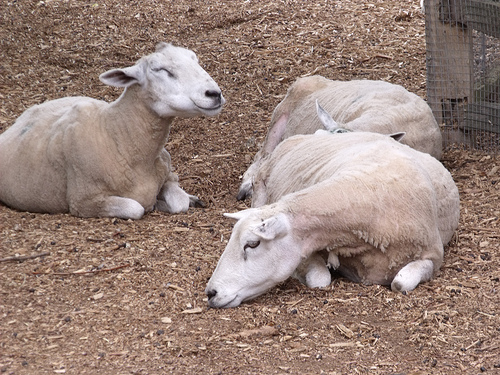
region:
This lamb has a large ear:
[257, 220, 284, 310]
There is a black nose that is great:
[207, 273, 229, 333]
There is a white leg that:
[163, 193, 182, 230]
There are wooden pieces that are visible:
[85, 285, 96, 314]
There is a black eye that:
[243, 228, 255, 251]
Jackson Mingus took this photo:
[138, 159, 226, 331]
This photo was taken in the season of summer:
[153, 143, 248, 367]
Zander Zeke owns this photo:
[166, 122, 223, 359]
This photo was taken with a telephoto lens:
[136, 150, 191, 337]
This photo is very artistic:
[160, 171, 242, 348]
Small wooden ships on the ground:
[15, 307, 72, 362]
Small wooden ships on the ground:
[428, 333, 480, 373]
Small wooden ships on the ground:
[330, 334, 386, 366]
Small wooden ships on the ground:
[282, 326, 328, 356]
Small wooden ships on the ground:
[212, 320, 282, 357]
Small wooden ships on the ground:
[148, 223, 190, 264]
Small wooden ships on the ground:
[193, 133, 224, 179]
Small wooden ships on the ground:
[305, 13, 363, 58]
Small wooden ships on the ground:
[235, 32, 276, 68]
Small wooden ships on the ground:
[31, 25, 78, 55]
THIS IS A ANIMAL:
[2, 43, 223, 220]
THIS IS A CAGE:
[404, 4, 498, 162]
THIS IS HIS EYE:
[239, 237, 264, 253]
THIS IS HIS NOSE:
[200, 287, 225, 302]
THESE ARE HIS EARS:
[217, 207, 284, 242]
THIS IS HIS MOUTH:
[212, 296, 245, 313]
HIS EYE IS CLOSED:
[150, 56, 177, 82]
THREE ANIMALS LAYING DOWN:
[3, 32, 463, 316]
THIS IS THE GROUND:
[0, 0, 498, 369]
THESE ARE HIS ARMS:
[97, 178, 197, 237]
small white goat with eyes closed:
[59, 38, 248, 196]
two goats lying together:
[258, 63, 467, 297]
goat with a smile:
[91, 45, 266, 127]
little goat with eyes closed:
[141, 48, 240, 105]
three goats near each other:
[22, 14, 460, 317]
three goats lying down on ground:
[104, 28, 429, 292]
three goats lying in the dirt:
[86, 36, 459, 353]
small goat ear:
[98, 53, 140, 93]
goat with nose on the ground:
[208, 203, 300, 337]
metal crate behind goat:
[423, 8, 499, 135]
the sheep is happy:
[83, 21, 237, 138]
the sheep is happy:
[96, 22, 240, 142]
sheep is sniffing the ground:
[176, 198, 306, 326]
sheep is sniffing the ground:
[179, 180, 296, 327]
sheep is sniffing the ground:
[180, 187, 295, 332]